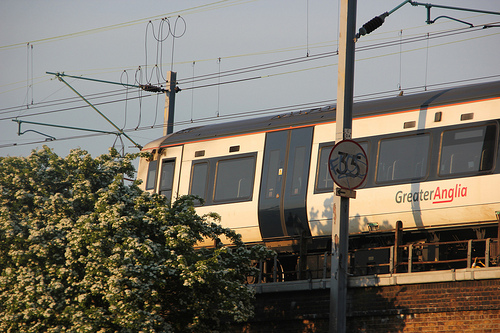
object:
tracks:
[218, 236, 500, 284]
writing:
[392, 183, 469, 204]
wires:
[0, 80, 152, 128]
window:
[191, 159, 217, 201]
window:
[377, 136, 427, 182]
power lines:
[0, 0, 224, 49]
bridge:
[239, 226, 500, 296]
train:
[127, 74, 499, 255]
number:
[335, 150, 362, 178]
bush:
[0, 146, 277, 332]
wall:
[244, 278, 500, 328]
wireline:
[357, 0, 500, 50]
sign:
[393, 183, 470, 206]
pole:
[328, 5, 362, 333]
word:
[394, 189, 434, 205]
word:
[432, 183, 469, 204]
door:
[257, 123, 313, 243]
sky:
[2, 2, 500, 84]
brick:
[446, 312, 461, 316]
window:
[214, 153, 256, 202]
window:
[159, 158, 175, 203]